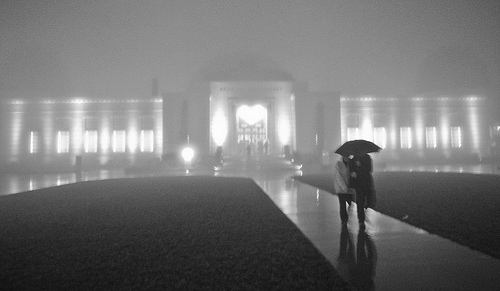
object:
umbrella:
[334, 140, 382, 159]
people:
[347, 153, 377, 230]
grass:
[0, 175, 347, 291]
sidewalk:
[251, 174, 498, 291]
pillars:
[183, 89, 211, 160]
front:
[168, 48, 323, 179]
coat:
[334, 159, 352, 194]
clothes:
[352, 152, 376, 227]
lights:
[460, 96, 483, 153]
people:
[246, 140, 270, 156]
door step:
[225, 152, 299, 172]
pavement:
[252, 166, 500, 291]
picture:
[0, 0, 500, 291]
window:
[28, 128, 43, 153]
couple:
[332, 152, 353, 221]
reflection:
[0, 168, 19, 191]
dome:
[0, 71, 40, 97]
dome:
[192, 44, 294, 80]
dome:
[411, 40, 499, 94]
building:
[0, 93, 36, 172]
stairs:
[219, 153, 303, 176]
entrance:
[226, 98, 277, 151]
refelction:
[279, 186, 293, 214]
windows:
[25, 130, 38, 155]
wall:
[0, 92, 500, 172]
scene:
[0, 0, 499, 291]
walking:
[338, 196, 371, 232]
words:
[231, 86, 283, 95]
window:
[229, 96, 273, 136]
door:
[241, 122, 260, 155]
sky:
[4, 1, 499, 100]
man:
[332, 154, 355, 228]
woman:
[334, 150, 354, 226]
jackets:
[334, 153, 378, 207]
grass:
[290, 170, 499, 261]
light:
[180, 147, 196, 164]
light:
[209, 100, 229, 148]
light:
[236, 103, 265, 125]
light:
[276, 107, 292, 146]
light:
[361, 114, 373, 143]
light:
[10, 100, 25, 163]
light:
[41, 100, 52, 157]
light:
[66, 96, 86, 165]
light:
[97, 113, 110, 162]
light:
[124, 119, 138, 155]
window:
[81, 129, 100, 153]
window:
[111, 128, 128, 154]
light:
[1, 169, 22, 198]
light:
[27, 171, 35, 191]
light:
[56, 175, 62, 186]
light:
[84, 173, 89, 183]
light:
[98, 170, 108, 179]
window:
[28, 130, 39, 155]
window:
[55, 128, 70, 153]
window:
[139, 127, 156, 152]